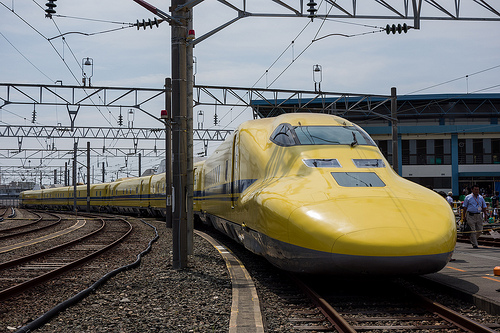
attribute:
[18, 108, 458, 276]
train — rounded, yellow, black, bright yellow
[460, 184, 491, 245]
man — walking, waiting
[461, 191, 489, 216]
shirt — blue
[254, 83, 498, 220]
building — blue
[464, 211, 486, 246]
pants — khaki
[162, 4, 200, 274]
pole — tall, wooden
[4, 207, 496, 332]
tracks — empty, brown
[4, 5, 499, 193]
sky — blue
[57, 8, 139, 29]
wire — black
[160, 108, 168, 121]
light — red